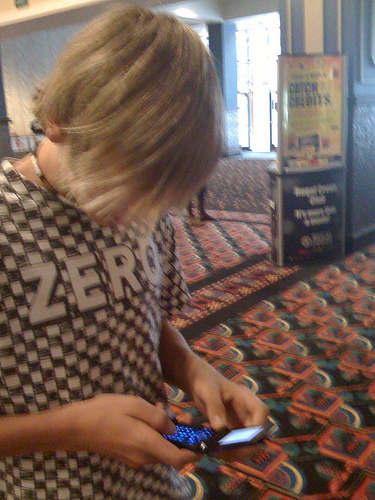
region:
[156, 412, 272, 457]
cell phone held in boys hands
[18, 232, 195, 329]
Zero is written on the boys shirt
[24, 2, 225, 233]
his hair is blonde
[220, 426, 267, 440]
the phone screen is blue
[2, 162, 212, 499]
his shirt is black and white checks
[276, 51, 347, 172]
a poster about a new movie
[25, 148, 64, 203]
a beaded necklace around his neck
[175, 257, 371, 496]
the carpet is multicolored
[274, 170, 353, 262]
the bottom promotion is written in black and white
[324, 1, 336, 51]
the molding is painted blue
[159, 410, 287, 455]
Flip phone in boy's hands.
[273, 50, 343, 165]
Yellow sign sitting on top of another sign.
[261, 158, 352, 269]
Black sign under yellow sign.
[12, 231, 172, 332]
White lettering on shirt ZERO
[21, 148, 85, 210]
Black brown and white necklace.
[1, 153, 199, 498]
Black and white checker t-shirt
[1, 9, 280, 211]
Entry way into building.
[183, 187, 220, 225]
Standing person's legs in background.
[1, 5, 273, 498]
Blonde boy using his phone.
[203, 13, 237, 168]
Black pillar in distance.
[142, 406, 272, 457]
Cell phone in person's hands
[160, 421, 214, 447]
Lit up blue keys of phone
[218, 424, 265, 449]
Lit up screen of cell phone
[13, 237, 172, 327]
Zero writing on checkered shirt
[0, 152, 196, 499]
Checkered shirt person is wearing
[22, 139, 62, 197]
Necklace person is wearing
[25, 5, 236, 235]
Long blonde hair of person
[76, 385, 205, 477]
right hand of person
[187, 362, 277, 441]
Left hand of person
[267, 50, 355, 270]
Advertising sign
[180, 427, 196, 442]
Blue lights on the cell phone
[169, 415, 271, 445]
An open cell phone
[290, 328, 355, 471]
A rug with a multicolored design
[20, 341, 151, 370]
The shirt is black and white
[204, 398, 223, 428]
The left thumb of the man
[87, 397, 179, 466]
The right hand of the man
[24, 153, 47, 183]
A necklace around his neck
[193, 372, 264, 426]
The left hand of the man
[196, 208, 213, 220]
The right foot of the other person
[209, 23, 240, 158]
A pillar behind the man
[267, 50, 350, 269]
regal club kiosk is black and grey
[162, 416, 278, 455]
kid has a flip phone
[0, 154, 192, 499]
person is wearing black and white shirt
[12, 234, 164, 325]
shirt says ZERO on the chest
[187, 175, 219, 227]
feet are below persons head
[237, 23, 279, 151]
theater doors are in background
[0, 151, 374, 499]
the flooring is carpet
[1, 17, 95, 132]
the wall is wooden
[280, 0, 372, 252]
pillar behind kiosk has green trim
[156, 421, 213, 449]
buttons are lit up blue